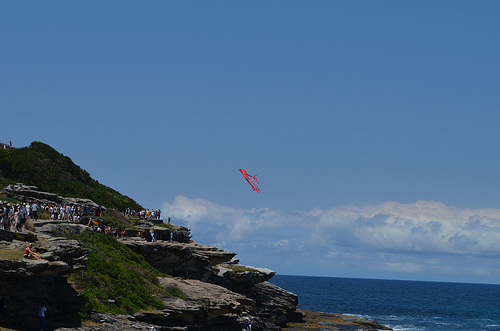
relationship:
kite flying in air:
[234, 166, 263, 194] [117, 137, 476, 263]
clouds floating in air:
[168, 198, 480, 252] [117, 137, 476, 263]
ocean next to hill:
[283, 275, 496, 329] [2, 143, 279, 330]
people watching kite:
[2, 197, 163, 232] [234, 166, 263, 194]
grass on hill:
[81, 238, 148, 305] [2, 143, 279, 330]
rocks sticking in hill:
[151, 239, 270, 305] [2, 143, 279, 330]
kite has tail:
[234, 166, 263, 194] [246, 175, 259, 193]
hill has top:
[2, 143, 279, 330] [2, 137, 48, 158]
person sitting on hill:
[20, 240, 42, 264] [2, 143, 279, 330]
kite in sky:
[234, 166, 263, 194] [5, 10, 492, 171]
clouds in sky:
[168, 198, 480, 252] [5, 10, 492, 171]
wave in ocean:
[337, 309, 437, 330] [283, 275, 496, 329]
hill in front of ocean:
[2, 143, 279, 330] [283, 275, 496, 329]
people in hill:
[2, 197, 163, 232] [2, 143, 279, 330]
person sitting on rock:
[20, 240, 42, 264] [5, 242, 72, 290]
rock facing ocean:
[5, 242, 72, 290] [283, 275, 496, 329]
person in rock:
[20, 240, 42, 264] [5, 242, 72, 290]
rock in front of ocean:
[5, 242, 72, 290] [283, 275, 496, 329]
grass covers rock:
[81, 238, 148, 305] [65, 230, 182, 320]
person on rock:
[20, 240, 42, 264] [5, 242, 72, 290]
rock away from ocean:
[5, 242, 72, 290] [283, 275, 496, 329]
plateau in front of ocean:
[299, 310, 372, 329] [283, 275, 496, 329]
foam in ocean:
[386, 321, 424, 329] [283, 275, 496, 329]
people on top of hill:
[2, 197, 163, 232] [2, 143, 279, 330]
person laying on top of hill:
[20, 240, 42, 264] [2, 143, 279, 330]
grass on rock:
[81, 238, 148, 305] [65, 230, 182, 320]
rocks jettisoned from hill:
[151, 239, 270, 305] [2, 143, 279, 330]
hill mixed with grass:
[2, 143, 279, 330] [81, 238, 148, 305]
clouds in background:
[168, 198, 480, 252] [30, 109, 493, 287]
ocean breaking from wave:
[283, 275, 496, 329] [337, 309, 437, 330]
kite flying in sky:
[234, 166, 263, 194] [5, 10, 492, 171]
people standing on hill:
[2, 197, 163, 232] [2, 143, 279, 330]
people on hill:
[2, 197, 163, 232] [2, 143, 279, 330]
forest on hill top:
[5, 145, 138, 208] [5, 143, 153, 226]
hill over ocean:
[2, 143, 279, 330] [283, 275, 496, 329]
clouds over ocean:
[168, 198, 480, 252] [283, 275, 496, 329]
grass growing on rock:
[81, 238, 148, 305] [65, 230, 182, 320]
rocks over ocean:
[151, 239, 270, 305] [283, 275, 496, 329]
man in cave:
[35, 301, 51, 322] [1, 264, 88, 331]